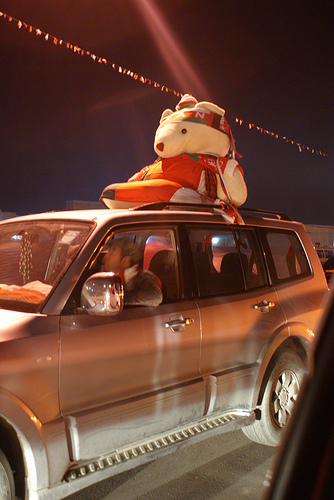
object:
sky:
[0, 0, 334, 226]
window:
[255, 226, 311, 285]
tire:
[239, 343, 309, 447]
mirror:
[86, 263, 139, 322]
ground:
[190, 441, 241, 476]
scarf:
[113, 263, 163, 289]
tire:
[229, 329, 324, 452]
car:
[2, 210, 327, 458]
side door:
[57, 222, 205, 460]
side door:
[182, 217, 290, 415]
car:
[10, 140, 331, 498]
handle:
[250, 298, 279, 313]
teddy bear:
[126, 93, 248, 207]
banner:
[0, 9, 333, 160]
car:
[3, 209, 331, 497]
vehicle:
[1, 219, 95, 315]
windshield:
[0, 199, 332, 498]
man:
[101, 231, 178, 317]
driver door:
[50, 190, 211, 472]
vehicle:
[1, 202, 326, 494]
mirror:
[79, 270, 123, 317]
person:
[96, 235, 164, 307]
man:
[98, 234, 161, 308]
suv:
[0, 209, 331, 498]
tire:
[241, 348, 305, 445]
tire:
[0, 454, 18, 497]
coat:
[122, 269, 163, 308]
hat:
[108, 236, 142, 266]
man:
[97, 238, 163, 310]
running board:
[63, 410, 254, 492]